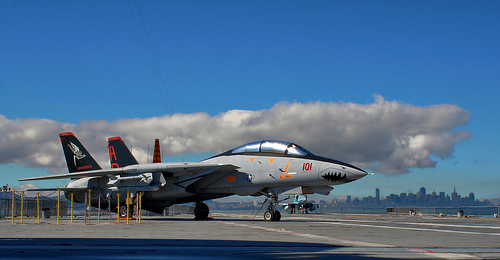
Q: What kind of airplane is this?
A: Fighter jet.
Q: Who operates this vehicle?
A: Fighter pilot.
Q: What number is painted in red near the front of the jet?
A: 101.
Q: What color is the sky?
A: Blue.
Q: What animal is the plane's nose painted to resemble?
A: Shark.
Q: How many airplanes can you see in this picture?
A: 2.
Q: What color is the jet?
A: Grey, black, and red.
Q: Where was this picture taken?
A: Airfield.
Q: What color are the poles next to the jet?
A: Yellow.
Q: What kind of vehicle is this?
A: Airplane.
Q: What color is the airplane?
A: Grey, blue and red.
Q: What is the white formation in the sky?
A: Cloud.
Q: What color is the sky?
A: Blue and white.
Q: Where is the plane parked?
A: Grey tarmac.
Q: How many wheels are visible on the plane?
A: Two.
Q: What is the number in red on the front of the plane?
A: 101.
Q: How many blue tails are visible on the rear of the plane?
A: Two.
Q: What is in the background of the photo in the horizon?
A: Cityscape.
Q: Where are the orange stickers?
A: On the plane.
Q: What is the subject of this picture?
A: A fighter jet.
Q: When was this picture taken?
A: During the day.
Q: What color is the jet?
A: Grey.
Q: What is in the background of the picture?
A: A city.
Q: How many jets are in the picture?
A: One.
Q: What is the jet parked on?
A: Concrete.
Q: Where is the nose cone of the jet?
A: On the front of it.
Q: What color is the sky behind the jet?
A: Blue.